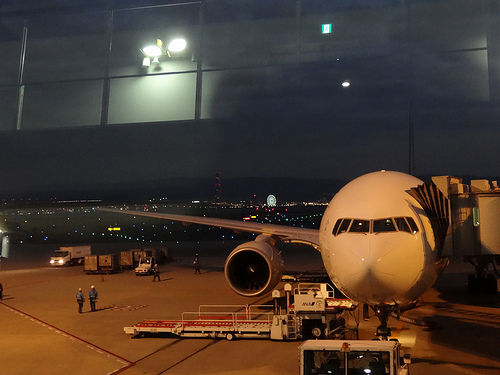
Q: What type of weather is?
A: It is overcast.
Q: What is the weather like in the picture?
A: It is overcast.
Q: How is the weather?
A: It is overcast.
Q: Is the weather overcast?
A: Yes, it is overcast.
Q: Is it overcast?
A: Yes, it is overcast.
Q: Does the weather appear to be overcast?
A: Yes, it is overcast.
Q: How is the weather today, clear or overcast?
A: It is overcast.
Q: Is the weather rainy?
A: No, it is overcast.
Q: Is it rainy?
A: No, it is overcast.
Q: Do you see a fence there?
A: No, there are no fences.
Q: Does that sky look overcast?
A: Yes, the sky is overcast.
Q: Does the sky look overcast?
A: Yes, the sky is overcast.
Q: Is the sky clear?
A: No, the sky is overcast.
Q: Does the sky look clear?
A: No, the sky is overcast.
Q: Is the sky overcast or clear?
A: The sky is overcast.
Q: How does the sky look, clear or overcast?
A: The sky is overcast.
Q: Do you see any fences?
A: No, there are no fences.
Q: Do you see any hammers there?
A: No, there are no hammers.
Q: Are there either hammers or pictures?
A: No, there are no hammers or pictures.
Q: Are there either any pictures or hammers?
A: No, there are no hammers or pictures.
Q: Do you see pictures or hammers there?
A: No, there are no hammers or pictures.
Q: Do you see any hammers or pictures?
A: No, there are no hammers or pictures.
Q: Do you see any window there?
A: Yes, there is a window.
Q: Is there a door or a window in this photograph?
A: Yes, there is a window.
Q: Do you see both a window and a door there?
A: No, there is a window but no doors.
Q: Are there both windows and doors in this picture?
A: No, there is a window but no doors.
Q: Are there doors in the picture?
A: No, there are no doors.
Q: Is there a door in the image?
A: No, there are no doors.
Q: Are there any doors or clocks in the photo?
A: No, there are no doors or clocks.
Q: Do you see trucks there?
A: Yes, there is a truck.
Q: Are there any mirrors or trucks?
A: Yes, there is a truck.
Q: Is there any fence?
A: No, there are no fences.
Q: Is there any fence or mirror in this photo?
A: No, there are no fences or mirrors.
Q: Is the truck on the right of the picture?
A: No, the truck is on the left of the image.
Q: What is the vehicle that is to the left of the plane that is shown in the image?
A: The vehicle is a truck.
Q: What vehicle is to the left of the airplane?
A: The vehicle is a truck.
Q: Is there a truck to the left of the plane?
A: Yes, there is a truck to the left of the plane.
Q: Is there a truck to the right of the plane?
A: No, the truck is to the left of the plane.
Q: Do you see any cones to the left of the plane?
A: No, there is a truck to the left of the plane.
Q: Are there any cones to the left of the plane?
A: No, there is a truck to the left of the plane.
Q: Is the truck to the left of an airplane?
A: Yes, the truck is to the left of an airplane.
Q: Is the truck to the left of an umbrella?
A: No, the truck is to the left of an airplane.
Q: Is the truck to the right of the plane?
A: No, the truck is to the left of the plane.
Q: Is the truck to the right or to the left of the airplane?
A: The truck is to the left of the airplane.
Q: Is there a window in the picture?
A: Yes, there is a window.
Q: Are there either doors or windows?
A: Yes, there is a window.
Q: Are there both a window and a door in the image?
A: No, there is a window but no doors.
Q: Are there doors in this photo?
A: No, there are no doors.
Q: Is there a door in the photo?
A: No, there are no doors.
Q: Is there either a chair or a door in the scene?
A: No, there are no doors or chairs.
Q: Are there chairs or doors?
A: No, there are no doors or chairs.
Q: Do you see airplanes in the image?
A: Yes, there is an airplane.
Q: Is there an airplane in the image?
A: Yes, there is an airplane.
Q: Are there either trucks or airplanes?
A: Yes, there is an airplane.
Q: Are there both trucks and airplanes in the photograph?
A: Yes, there are both an airplane and a truck.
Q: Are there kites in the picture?
A: No, there are no kites.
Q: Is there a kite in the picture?
A: No, there are no kites.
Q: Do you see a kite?
A: No, there are no kites.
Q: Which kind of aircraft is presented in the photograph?
A: The aircraft is an airplane.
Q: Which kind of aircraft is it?
A: The aircraft is an airplane.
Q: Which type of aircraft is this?
A: This is an airplane.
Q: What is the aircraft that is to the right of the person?
A: The aircraft is an airplane.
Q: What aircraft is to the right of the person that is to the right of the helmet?
A: The aircraft is an airplane.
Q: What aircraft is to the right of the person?
A: The aircraft is an airplane.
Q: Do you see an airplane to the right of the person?
A: Yes, there is an airplane to the right of the person.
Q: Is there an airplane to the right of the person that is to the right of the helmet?
A: Yes, there is an airplane to the right of the person.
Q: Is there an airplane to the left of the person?
A: No, the airplane is to the right of the person.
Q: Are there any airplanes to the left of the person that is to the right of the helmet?
A: No, the airplane is to the right of the person.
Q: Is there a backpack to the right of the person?
A: No, there is an airplane to the right of the person.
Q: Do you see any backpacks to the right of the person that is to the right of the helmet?
A: No, there is an airplane to the right of the person.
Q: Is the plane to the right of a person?
A: Yes, the plane is to the right of a person.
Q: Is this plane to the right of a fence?
A: No, the plane is to the right of a person.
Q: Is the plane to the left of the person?
A: No, the plane is to the right of the person.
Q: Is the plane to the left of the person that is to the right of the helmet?
A: No, the plane is to the right of the person.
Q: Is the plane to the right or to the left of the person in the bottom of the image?
A: The plane is to the right of the person.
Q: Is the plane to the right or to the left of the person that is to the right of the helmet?
A: The plane is to the right of the person.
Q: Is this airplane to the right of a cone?
A: No, the airplane is to the right of the helmet.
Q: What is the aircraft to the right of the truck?
A: The aircraft is an airplane.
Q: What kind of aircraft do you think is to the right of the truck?
A: The aircraft is an airplane.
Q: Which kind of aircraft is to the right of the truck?
A: The aircraft is an airplane.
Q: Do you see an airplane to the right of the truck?
A: Yes, there is an airplane to the right of the truck.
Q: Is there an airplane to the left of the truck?
A: No, the airplane is to the right of the truck.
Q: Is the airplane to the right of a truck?
A: Yes, the airplane is to the right of a truck.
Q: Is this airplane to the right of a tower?
A: No, the airplane is to the right of a truck.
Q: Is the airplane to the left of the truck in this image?
A: No, the airplane is to the right of the truck.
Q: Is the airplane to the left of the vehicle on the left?
A: No, the airplane is to the right of the truck.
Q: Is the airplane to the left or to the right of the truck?
A: The airplane is to the right of the truck.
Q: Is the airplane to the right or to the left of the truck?
A: The airplane is to the right of the truck.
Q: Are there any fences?
A: No, there are no fences.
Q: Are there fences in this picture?
A: No, there are no fences.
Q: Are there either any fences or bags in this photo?
A: No, there are no fences or bags.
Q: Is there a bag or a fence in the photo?
A: No, there are no fences or bags.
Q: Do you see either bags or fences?
A: No, there are no fences or bags.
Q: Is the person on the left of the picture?
A: Yes, the person is on the left of the image.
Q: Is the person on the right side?
A: No, the person is on the left of the image.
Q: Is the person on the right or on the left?
A: The person is on the left of the image.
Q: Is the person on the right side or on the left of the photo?
A: The person is on the left of the image.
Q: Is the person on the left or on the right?
A: The person is on the left of the image.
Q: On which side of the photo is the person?
A: The person is on the left of the image.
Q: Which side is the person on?
A: The person is on the left of the image.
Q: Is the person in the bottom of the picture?
A: Yes, the person is in the bottom of the image.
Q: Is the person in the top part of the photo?
A: No, the person is in the bottom of the image.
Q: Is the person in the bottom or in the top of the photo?
A: The person is in the bottom of the image.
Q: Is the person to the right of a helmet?
A: Yes, the person is to the right of a helmet.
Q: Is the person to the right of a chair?
A: No, the person is to the right of a helmet.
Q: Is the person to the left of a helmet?
A: No, the person is to the right of a helmet.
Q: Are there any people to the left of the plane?
A: Yes, there is a person to the left of the plane.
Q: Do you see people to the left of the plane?
A: Yes, there is a person to the left of the plane.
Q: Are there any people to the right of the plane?
A: No, the person is to the left of the plane.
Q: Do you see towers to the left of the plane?
A: No, there is a person to the left of the plane.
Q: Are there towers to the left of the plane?
A: No, there is a person to the left of the plane.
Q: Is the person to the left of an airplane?
A: Yes, the person is to the left of an airplane.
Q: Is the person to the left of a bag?
A: No, the person is to the left of an airplane.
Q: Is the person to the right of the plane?
A: No, the person is to the left of the plane.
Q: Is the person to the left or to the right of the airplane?
A: The person is to the left of the airplane.